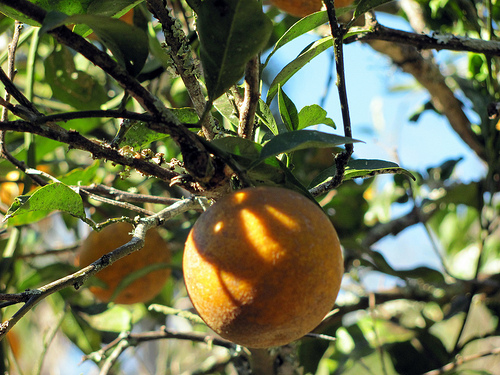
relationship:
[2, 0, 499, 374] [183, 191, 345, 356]
orange tree has fruit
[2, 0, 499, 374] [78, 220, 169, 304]
orange tree has fruit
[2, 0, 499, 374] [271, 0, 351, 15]
orange tree has fruit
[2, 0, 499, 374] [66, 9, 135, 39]
orange tree has fruit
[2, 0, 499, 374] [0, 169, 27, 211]
orange tree has fruit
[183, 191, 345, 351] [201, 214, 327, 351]
fruit has tan markings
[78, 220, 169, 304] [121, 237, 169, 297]
fruit has discoloration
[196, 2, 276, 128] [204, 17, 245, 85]
leaf has scale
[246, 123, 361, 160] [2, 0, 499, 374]
leaf on orange tree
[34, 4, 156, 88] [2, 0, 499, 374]
leaf on orange tree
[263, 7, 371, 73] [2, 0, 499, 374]
leaf on orange tree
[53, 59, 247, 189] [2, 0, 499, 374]
leaf on orange tree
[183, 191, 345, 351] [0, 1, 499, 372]
fruit are on branches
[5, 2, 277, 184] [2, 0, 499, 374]
branches on orange tree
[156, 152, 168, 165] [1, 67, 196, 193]
bud on a branch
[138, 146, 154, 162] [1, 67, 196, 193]
bud on a branch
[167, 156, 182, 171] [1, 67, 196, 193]
bud on a branch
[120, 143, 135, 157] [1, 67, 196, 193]
bud on a branch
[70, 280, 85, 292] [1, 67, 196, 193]
bud on a branch